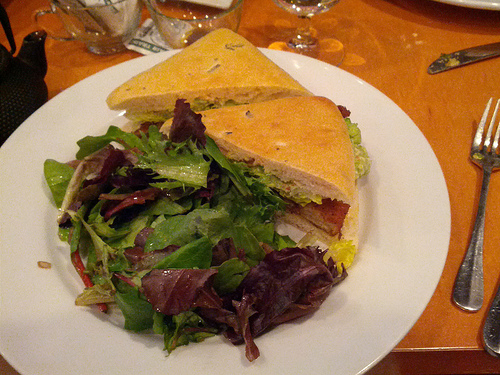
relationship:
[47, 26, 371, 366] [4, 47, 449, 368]
food on plate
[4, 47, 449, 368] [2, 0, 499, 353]
plate on table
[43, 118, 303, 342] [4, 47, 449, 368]
leaves on plate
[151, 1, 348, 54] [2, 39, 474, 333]
glasses on table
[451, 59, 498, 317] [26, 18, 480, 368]
silverware on table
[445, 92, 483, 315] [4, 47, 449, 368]
fork next to plate